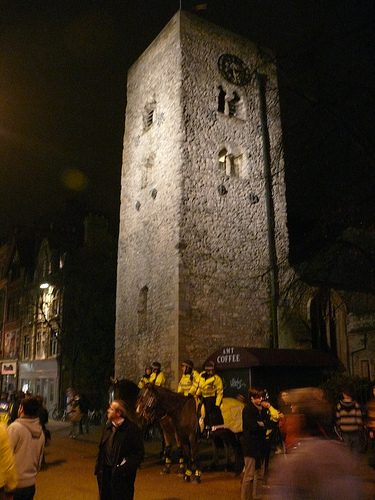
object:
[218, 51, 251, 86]
clock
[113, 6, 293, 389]
tower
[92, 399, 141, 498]
man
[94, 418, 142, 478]
jacket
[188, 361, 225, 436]
policeman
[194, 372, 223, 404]
jacket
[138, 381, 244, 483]
horse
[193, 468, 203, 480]
bootie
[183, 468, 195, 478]
bootie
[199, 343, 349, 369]
awning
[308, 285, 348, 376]
entrance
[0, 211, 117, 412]
house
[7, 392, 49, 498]
person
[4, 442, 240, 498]
street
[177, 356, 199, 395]
policeman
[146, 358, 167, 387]
policeman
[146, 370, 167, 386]
jacket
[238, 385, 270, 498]
man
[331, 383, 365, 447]
person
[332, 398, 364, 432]
hoodie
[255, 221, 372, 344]
tree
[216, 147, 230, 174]
window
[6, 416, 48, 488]
hoodie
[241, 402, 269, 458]
coat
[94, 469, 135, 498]
pants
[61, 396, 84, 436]
person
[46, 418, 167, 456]
sidewalk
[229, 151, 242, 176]
window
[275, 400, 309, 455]
woman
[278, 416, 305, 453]
dress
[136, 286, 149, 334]
window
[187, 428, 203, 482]
leg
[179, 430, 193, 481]
leg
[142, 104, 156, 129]
vent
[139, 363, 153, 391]
policeman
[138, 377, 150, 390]
vest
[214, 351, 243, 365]
text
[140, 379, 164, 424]
head